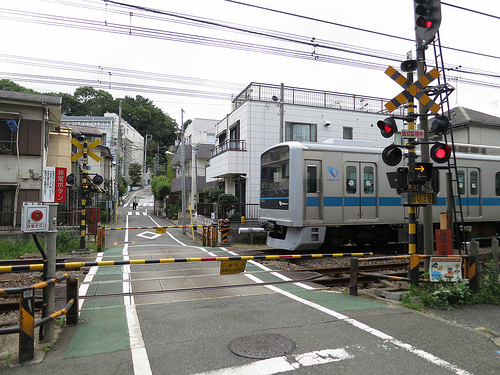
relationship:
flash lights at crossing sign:
[403, 92, 463, 191] [382, 64, 439, 112]